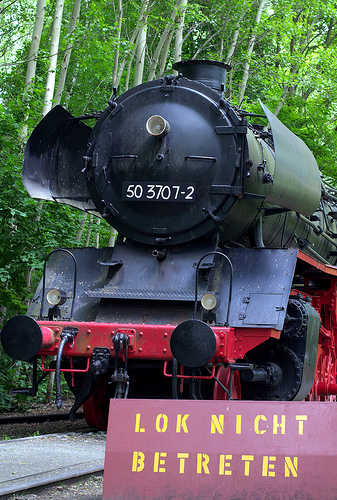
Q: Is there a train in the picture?
A: Yes, there is a train.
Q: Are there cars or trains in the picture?
A: Yes, there is a train.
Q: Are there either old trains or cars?
A: Yes, there is an old train.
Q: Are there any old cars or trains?
A: Yes, there is an old train.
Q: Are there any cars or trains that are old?
A: Yes, the train is old.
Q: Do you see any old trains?
A: Yes, there is an old train.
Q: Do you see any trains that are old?
A: Yes, there is a train that is old.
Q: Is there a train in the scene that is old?
A: Yes, there is a train that is old.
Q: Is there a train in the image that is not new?
A: Yes, there is a old train.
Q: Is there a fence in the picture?
A: No, there are no fences.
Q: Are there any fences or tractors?
A: No, there are no fences or tractors.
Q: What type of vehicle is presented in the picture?
A: The vehicle is a train.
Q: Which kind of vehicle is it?
A: The vehicle is a train.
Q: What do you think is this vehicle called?
A: This is a train.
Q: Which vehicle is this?
A: This is a train.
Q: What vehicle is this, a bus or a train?
A: This is a train.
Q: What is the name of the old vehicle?
A: The vehicle is a train.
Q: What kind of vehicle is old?
A: The vehicle is a train.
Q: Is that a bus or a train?
A: That is a train.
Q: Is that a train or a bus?
A: That is a train.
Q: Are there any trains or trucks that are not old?
A: No, there is a train but it is old.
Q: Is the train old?
A: Yes, the train is old.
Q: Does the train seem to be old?
A: Yes, the train is old.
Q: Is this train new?
A: No, the train is old.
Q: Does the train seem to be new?
A: No, the train is old.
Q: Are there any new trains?
A: No, there is a train but it is old.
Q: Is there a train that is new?
A: No, there is a train but it is old.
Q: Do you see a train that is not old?
A: No, there is a train but it is old.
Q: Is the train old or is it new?
A: The train is old.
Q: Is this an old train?
A: Yes, this is an old train.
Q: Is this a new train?
A: No, this is an old train.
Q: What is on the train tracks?
A: The train is on the train tracks.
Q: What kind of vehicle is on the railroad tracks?
A: The vehicle is a train.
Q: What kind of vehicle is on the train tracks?
A: The vehicle is a train.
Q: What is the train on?
A: The train is on the tracks.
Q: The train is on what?
A: The train is on the tracks.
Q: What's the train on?
A: The train is on the tracks.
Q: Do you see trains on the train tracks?
A: Yes, there is a train on the train tracks.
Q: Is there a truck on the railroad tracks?
A: No, there is a train on the railroad tracks.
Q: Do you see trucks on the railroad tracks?
A: No, there is a train on the railroad tracks.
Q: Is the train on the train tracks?
A: Yes, the train is on the train tracks.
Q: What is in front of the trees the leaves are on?
A: The train is in front of the trees.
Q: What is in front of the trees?
A: The train is in front of the trees.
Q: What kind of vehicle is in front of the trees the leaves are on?
A: The vehicle is a train.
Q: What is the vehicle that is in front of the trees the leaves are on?
A: The vehicle is a train.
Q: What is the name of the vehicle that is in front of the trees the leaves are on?
A: The vehicle is a train.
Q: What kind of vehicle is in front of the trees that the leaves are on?
A: The vehicle is a train.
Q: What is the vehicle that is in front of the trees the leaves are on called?
A: The vehicle is a train.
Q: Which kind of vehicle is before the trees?
A: The vehicle is a train.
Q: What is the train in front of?
A: The train is in front of the trees.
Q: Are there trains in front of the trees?
A: Yes, there is a train in front of the trees.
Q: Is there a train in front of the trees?
A: Yes, there is a train in front of the trees.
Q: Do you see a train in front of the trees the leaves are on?
A: Yes, there is a train in front of the trees.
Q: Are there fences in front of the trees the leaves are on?
A: No, there is a train in front of the trees.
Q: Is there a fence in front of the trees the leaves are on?
A: No, there is a train in front of the trees.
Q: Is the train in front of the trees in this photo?
A: Yes, the train is in front of the trees.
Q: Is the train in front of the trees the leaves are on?
A: Yes, the train is in front of the trees.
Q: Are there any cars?
A: No, there are no cars.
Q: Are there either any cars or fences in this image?
A: No, there are no cars or fences.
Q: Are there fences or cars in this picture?
A: No, there are no cars or fences.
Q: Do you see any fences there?
A: No, there are no fences.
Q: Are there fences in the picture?
A: No, there are no fences.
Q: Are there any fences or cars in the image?
A: No, there are no fences or cars.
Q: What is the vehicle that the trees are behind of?
A: The vehicle is a train.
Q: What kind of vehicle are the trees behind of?
A: The trees are behind the train.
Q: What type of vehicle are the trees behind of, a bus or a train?
A: The trees are behind a train.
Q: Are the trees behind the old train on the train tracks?
A: Yes, the trees are behind the train.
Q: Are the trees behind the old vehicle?
A: Yes, the trees are behind the train.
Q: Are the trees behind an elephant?
A: No, the trees are behind the train.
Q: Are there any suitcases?
A: No, there are no suitcases.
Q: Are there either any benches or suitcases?
A: No, there are no suitcases or benches.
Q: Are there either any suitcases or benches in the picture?
A: No, there are no suitcases or benches.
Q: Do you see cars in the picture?
A: No, there are no cars.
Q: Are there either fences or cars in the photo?
A: No, there are no cars or fences.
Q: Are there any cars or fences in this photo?
A: No, there are no cars or fences.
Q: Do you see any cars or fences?
A: No, there are no cars or fences.